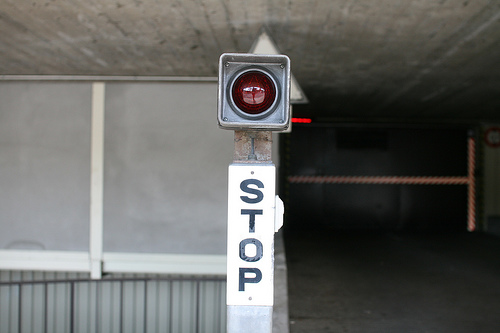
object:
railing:
[1, 269, 227, 331]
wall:
[1, 78, 233, 331]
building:
[2, 0, 484, 329]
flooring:
[284, 213, 483, 330]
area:
[1, 0, 500, 331]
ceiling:
[2, 1, 484, 123]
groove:
[8, 0, 110, 73]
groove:
[221, 0, 240, 56]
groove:
[141, 15, 197, 76]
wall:
[281, 121, 483, 219]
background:
[281, 101, 484, 233]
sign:
[225, 165, 275, 306]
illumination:
[292, 118, 311, 123]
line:
[87, 75, 107, 279]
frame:
[0, 250, 225, 275]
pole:
[466, 138, 476, 232]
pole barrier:
[281, 137, 474, 233]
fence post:
[15, 281, 22, 331]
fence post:
[42, 281, 49, 331]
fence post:
[68, 282, 77, 331]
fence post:
[117, 277, 125, 329]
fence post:
[142, 274, 151, 331]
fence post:
[166, 276, 175, 331]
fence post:
[193, 277, 203, 331]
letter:
[239, 178, 262, 294]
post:
[222, 34, 274, 333]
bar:
[290, 175, 475, 185]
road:
[281, 229, 500, 333]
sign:
[484, 130, 500, 144]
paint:
[270, 192, 285, 234]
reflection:
[237, 86, 267, 106]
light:
[217, 51, 289, 130]